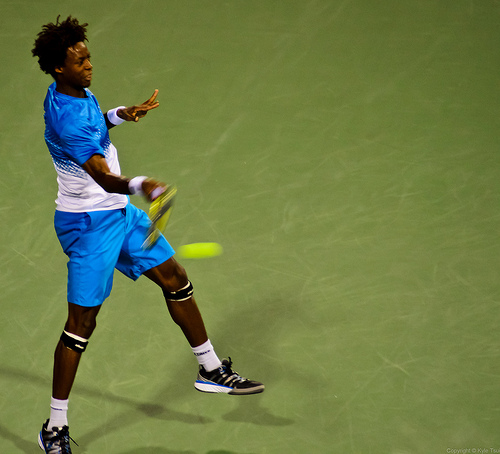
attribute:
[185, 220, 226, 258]
ball — tennis, yellow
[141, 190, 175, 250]
racket — tennis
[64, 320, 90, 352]
band — black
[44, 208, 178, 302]
short — blue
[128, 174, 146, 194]
band — white, wrist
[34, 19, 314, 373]
tennis player — playing tennis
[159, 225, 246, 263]
ball — mid air, green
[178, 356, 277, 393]
sneaker — black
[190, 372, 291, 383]
sneaker — black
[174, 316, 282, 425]
sock — white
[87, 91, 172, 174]
wristband — white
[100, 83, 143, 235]
wristband — white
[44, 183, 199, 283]
shorts — blue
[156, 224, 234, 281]
ball — in air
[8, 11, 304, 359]
man — white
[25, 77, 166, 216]
shirt — blue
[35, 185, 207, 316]
drawers — blue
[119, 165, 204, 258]
bat — green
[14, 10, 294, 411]
man — playing tennis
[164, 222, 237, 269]
ball — mid air, green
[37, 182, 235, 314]
shorts — blue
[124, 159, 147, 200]
band — white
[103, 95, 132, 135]
band — white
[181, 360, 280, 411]
sneakers — black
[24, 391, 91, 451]
sneakers — black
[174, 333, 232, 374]
sock — white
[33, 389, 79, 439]
sock — white